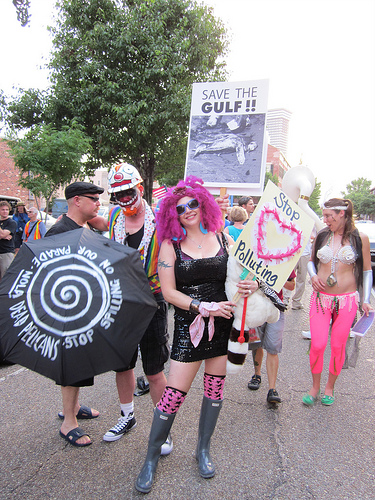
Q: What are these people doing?
A: Protesting.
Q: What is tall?
A: Trees.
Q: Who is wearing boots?
A: Woman in front.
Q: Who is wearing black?
A: Woman in front.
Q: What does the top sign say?
A: "SAVE THE GULF !!".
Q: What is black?
A: Umbrella.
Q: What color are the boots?
A: Black.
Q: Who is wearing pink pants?
A: Woman on right.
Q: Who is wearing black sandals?
A: Man on left.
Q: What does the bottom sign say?
A: "Stop Polluting".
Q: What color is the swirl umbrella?
A: Black and white.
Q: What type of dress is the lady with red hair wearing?
A: Black sequin tight dress.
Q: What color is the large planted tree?
A: Green.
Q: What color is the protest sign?
A: Black and white.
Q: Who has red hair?
A: Lady wearing black sequin dress.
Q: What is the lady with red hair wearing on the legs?
A: Grey boots.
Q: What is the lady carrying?
A: A stuffed animal.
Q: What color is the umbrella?
A: Black and white.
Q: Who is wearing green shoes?
A: Lady wearing pink pants.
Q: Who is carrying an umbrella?
A: Man wearing black flip flops.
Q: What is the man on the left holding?
A: An umbrella.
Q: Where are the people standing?
A: In the street.